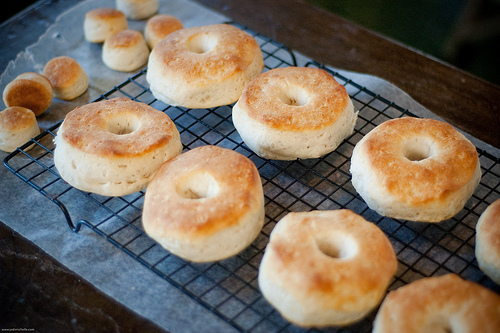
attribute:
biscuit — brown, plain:
[146, 24, 263, 109]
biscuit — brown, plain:
[232, 66, 360, 160]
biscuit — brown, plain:
[350, 116, 483, 223]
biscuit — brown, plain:
[142, 146, 265, 264]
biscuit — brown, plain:
[258, 208, 398, 328]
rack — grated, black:
[3, 22, 499, 332]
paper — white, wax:
[0, 0, 499, 332]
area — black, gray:
[8, 49, 498, 331]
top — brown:
[151, 23, 259, 83]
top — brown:
[240, 66, 348, 131]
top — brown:
[366, 117, 478, 204]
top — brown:
[62, 97, 174, 158]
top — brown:
[145, 144, 255, 239]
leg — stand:
[56, 201, 94, 234]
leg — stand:
[285, 42, 318, 67]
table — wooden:
[1, 0, 498, 332]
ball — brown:
[1, 105, 41, 154]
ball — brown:
[3, 71, 53, 117]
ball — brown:
[44, 56, 89, 101]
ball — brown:
[102, 28, 152, 72]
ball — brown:
[83, 8, 127, 44]